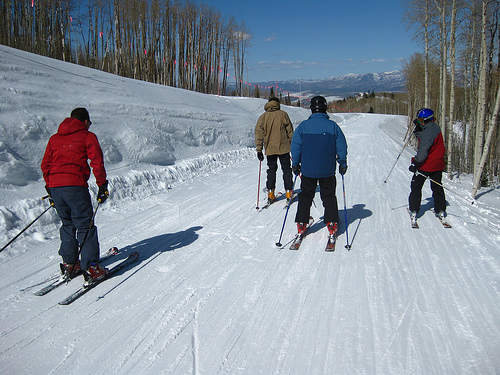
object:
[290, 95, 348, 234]
people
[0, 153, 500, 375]
field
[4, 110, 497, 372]
floor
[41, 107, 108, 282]
man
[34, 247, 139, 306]
skiingboards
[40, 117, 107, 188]
jacket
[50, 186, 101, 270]
pants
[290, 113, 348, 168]
jacket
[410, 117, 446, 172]
jacket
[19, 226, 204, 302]
shadow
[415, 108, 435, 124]
helmet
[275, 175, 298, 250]
skiing stick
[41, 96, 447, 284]
group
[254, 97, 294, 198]
person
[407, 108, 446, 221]
person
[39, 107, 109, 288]
skier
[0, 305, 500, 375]
snow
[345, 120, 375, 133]
snow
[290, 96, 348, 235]
skier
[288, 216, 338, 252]
pair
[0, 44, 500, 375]
ground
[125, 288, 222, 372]
track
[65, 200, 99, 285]
ski pole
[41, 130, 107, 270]
body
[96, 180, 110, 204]
glove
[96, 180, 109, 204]
hand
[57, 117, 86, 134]
hood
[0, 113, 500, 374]
ski trail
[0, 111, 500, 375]
ski course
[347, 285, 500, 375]
tracks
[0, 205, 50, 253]
ski poles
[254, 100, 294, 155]
jacket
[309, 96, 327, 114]
helmet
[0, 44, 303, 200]
slope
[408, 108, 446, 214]
skier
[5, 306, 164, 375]
trail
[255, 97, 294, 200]
skier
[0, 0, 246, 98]
markers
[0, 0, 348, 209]
area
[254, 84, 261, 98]
trees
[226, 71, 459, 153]
distance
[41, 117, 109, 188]
snow jacket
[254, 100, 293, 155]
coat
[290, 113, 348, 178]
coat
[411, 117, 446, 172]
coat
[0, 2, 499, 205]
scenery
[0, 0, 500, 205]
background